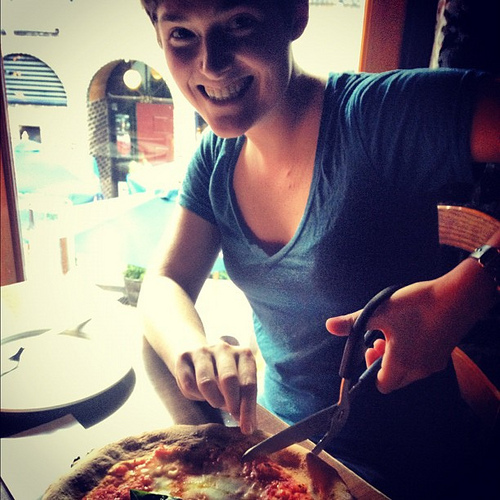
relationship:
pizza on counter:
[81, 424, 333, 499] [11, 363, 401, 498]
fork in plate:
[2, 311, 94, 376] [2, 308, 137, 413]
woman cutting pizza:
[101, 4, 498, 494] [89, 427, 304, 499]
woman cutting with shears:
[101, 4, 498, 494] [226, 277, 392, 472]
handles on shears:
[339, 283, 399, 396] [241, 284, 397, 454]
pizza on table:
[81, 424, 333, 499] [23, 285, 122, 331]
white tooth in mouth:
[203, 87, 215, 97] [192, 73, 255, 108]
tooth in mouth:
[224, 89, 229, 98] [196, 73, 253, 103]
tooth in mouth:
[224, 89, 229, 98] [190, 72, 259, 109]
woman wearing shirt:
[101, 4, 498, 494] [173, 78, 451, 445]